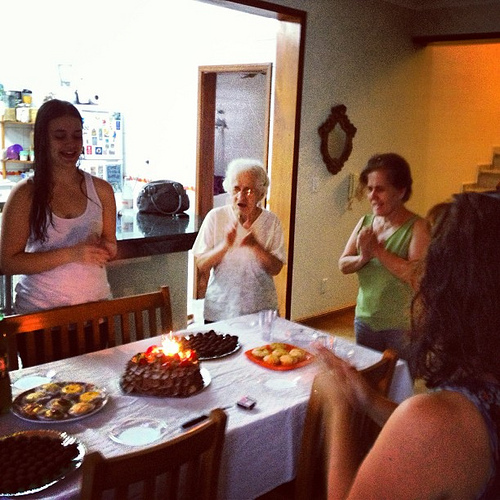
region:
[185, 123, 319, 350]
This is a person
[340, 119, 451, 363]
This is a person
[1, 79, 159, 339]
This is a person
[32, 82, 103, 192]
Head of a person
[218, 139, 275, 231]
Head of a person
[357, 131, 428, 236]
Head of a person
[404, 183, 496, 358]
Head of a person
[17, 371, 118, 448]
This is food on a plate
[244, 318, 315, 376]
This is food on a plate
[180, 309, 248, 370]
This is food on a plate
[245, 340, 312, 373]
orange square plate full of food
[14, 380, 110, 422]
round silver plate full of food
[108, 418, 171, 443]
round plastic plate sitting on table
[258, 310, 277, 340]
stack of clear plastic cups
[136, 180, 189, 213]
grey purse sitting on island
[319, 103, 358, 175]
brass mirror affixed to wall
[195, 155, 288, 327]
older woman standing near table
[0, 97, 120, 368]
teen girl with long hair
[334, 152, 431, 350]
middle aged woman standing near table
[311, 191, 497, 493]
woman with curly hair sitting at table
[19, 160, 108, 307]
the woman is wearing a tank top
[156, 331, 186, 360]
a candle is on a cake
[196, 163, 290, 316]
an elderly lady is clapping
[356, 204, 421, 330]
the woman is middle age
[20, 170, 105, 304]
the tank top is white in color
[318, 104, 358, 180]
a mirror is hanging on the wall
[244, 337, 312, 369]
food is on a dish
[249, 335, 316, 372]
the dish is orange in color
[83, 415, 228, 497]
the chair is made of wood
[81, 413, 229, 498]
the chair is brown in color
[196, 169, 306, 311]
the woman has glases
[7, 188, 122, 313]
the woman is in vest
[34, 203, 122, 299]
the vest is white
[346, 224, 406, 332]
the vest is gren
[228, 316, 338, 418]
table clothe is white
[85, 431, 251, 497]
the chair is wooden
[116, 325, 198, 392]
the cake has lights on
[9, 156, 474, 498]
the people are celebrating a birthday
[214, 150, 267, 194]
the hair is white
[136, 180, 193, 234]
the bag is black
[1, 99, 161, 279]
girl next to the table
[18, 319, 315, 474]
food on the table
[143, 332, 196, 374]
candles on the cake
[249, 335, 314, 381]
food on a red plate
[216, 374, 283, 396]
white tablecloth under the table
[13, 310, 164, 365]
chairs next to the table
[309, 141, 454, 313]
lady wearing a green shirt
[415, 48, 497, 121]
light in the background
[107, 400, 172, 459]
white plate on the table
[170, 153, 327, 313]
old lady in the photo